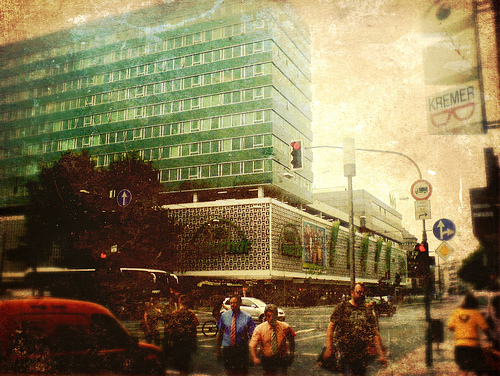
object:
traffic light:
[290, 139, 303, 171]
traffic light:
[415, 242, 429, 276]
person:
[213, 294, 255, 375]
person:
[250, 301, 297, 374]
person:
[164, 291, 200, 374]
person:
[321, 281, 389, 374]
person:
[140, 297, 164, 344]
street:
[120, 293, 465, 376]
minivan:
[0, 294, 165, 374]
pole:
[340, 133, 362, 307]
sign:
[431, 217, 457, 242]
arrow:
[446, 226, 454, 236]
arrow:
[436, 217, 446, 230]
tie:
[229, 312, 237, 347]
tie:
[270, 325, 280, 360]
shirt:
[217, 308, 256, 346]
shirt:
[250, 320, 297, 357]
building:
[3, 2, 313, 305]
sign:
[425, 80, 484, 135]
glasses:
[430, 101, 474, 128]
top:
[330, 299, 380, 362]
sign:
[409, 178, 434, 201]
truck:
[413, 185, 431, 195]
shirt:
[448, 307, 489, 345]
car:
[220, 293, 285, 329]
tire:
[201, 319, 220, 338]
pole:
[422, 270, 434, 367]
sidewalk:
[376, 339, 500, 374]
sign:
[300, 215, 328, 271]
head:
[225, 292, 242, 312]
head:
[263, 299, 279, 327]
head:
[351, 279, 367, 305]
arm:
[213, 315, 223, 359]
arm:
[248, 325, 260, 364]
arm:
[282, 322, 297, 361]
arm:
[322, 301, 344, 360]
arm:
[370, 306, 389, 368]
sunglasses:
[354, 288, 368, 296]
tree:
[16, 145, 183, 307]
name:
[186, 233, 254, 261]